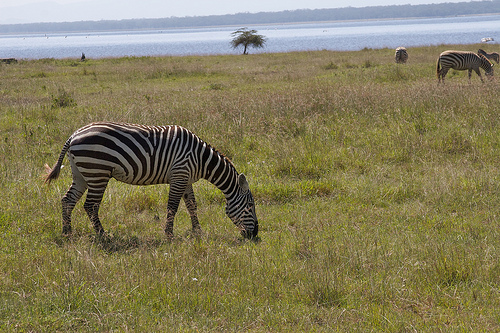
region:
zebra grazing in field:
[46, 118, 261, 243]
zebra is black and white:
[91, 126, 184, 168]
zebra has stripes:
[42, 120, 263, 247]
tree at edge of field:
[227, 27, 267, 56]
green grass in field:
[307, 98, 496, 241]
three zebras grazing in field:
[396, 44, 498, 86]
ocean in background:
[42, 33, 226, 54]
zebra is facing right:
[49, 118, 260, 244]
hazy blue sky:
[7, 1, 75, 18]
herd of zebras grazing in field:
[45, 47, 496, 247]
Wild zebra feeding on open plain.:
[40, 124, 259, 244]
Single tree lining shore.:
[231, 22, 265, 54]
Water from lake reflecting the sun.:
[21, 31, 218, 51]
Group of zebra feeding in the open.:
[396, 44, 499, 83]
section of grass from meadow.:
[310, 198, 493, 323]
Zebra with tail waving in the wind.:
[42, 118, 258, 248]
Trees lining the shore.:
[0, 0, 499, 34]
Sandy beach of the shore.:
[127, 8, 499, 33]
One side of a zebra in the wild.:
[38, 118, 263, 244]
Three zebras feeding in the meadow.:
[393, 45, 498, 82]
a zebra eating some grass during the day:
[46, 117, 262, 252]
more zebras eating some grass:
[388, 40, 497, 73]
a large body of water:
[2, 1, 487, 61]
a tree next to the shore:
[231, 23, 264, 55]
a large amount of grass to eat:
[268, 60, 498, 326]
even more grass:
[25, 62, 289, 125]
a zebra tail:
[46, 135, 73, 185]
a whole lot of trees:
[5, 7, 492, 24]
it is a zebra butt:
[396, 45, 409, 66]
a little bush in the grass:
[51, 82, 76, 112]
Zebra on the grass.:
[14, 91, 323, 268]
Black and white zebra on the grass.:
[7, 98, 399, 316]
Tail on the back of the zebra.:
[24, 143, 85, 198]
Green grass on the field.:
[50, 219, 357, 319]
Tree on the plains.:
[213, 13, 300, 65]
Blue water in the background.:
[37, 15, 418, 106]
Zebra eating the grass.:
[183, 127, 287, 279]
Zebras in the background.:
[354, 25, 498, 101]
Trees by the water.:
[212, 7, 431, 37]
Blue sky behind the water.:
[104, 1, 309, 118]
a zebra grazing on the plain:
[40, 121, 262, 243]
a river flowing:
[295, 22, 467, 43]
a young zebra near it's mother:
[477, 43, 499, 63]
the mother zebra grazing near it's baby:
[432, 50, 498, 85]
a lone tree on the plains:
[226, 25, 267, 60]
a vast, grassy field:
[238, 78, 435, 170]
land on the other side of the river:
[60, 13, 390, 28]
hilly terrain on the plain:
[220, 63, 431, 145]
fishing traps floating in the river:
[15, 33, 100, 41]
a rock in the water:
[474, 34, 497, 46]